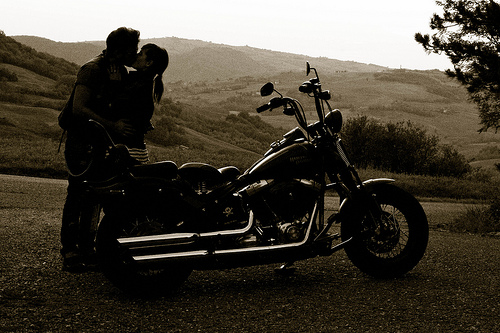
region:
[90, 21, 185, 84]
A couple kissing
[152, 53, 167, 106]
A woman's pony tail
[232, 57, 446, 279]
The front of a motor sycle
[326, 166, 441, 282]
a front motorcycle tire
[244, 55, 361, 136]
motorcycle handles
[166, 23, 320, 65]
mountain range and sky in the distance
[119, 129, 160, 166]
woman wearing a striped black and white skirt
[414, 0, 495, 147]
leaves on a tree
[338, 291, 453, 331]
gravel on the ground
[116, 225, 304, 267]
Two motorcycle mufflers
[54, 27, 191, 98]
They are kissing.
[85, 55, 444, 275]
The motorcycle is black.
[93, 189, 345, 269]
The exhaust is long.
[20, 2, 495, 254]
They are in the hills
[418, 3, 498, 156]
The tree is leafy.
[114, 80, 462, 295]
The bike is metal and black.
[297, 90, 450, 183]
The bush is lush.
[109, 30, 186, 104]
She is wearing a pony tail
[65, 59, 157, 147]
The is wearing a jacket.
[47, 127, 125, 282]
He is wearing jeans.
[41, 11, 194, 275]
A man and woman kissing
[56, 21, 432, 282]
man and woman next to motorcycle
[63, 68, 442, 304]
A black and chrome motorcycle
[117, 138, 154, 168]
Tail of black and white shirt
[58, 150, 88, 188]
A chain on man's leg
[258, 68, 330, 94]
Mirrors on top of handlebars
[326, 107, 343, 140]
One front headlight on bike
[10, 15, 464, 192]
Rolling hills behind people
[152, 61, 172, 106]
Woman has a pony tail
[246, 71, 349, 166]
Handle bars of motorcycle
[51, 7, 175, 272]
shadowed couple kissing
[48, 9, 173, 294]
couple embracing with moutains in background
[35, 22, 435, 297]
couple embracing by motorcycle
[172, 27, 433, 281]
shadowed motorcycle with moutains in background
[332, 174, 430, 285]
one front motorcycle wheel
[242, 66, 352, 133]
two motorcycle handlebars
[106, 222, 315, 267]
two shiny chrome motorcycle exhaust pipes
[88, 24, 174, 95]
side view of man and woman kissing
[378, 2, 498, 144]
shadowed view of tree and mountains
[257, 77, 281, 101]
one front motorcycle mirror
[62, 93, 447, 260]
motorcycle is black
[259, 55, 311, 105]
motorcycle has two mirrors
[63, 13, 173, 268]
two people are embracing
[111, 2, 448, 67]
sky is grey and overcast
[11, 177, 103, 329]
road is bare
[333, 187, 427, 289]
wheels are dark and in shadow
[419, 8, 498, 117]
thin tree behind road and cycle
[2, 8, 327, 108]
large hill in background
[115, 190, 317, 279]
exhaust pipes are reflective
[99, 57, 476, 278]
motorcycle is large